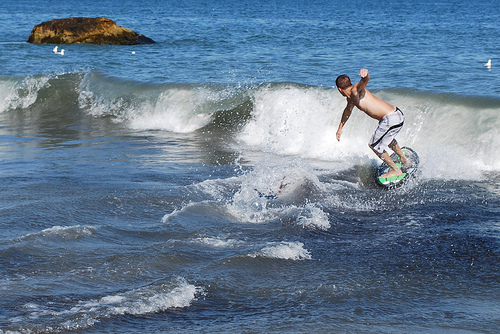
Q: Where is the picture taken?
A: The beach.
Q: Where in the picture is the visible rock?
A: On the left.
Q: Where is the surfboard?
A: In the water.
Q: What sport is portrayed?
A: Surfing.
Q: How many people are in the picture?
A: 1.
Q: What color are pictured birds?
A: White.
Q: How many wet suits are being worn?
A: None.